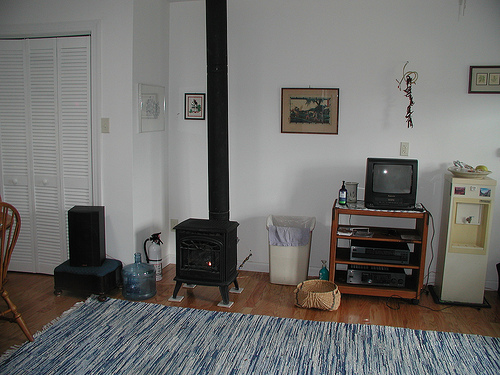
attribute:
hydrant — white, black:
[129, 225, 189, 286]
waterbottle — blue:
[121, 247, 158, 297]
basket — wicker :
[280, 248, 356, 315]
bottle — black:
[335, 180, 351, 207]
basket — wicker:
[290, 279, 341, 312]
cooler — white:
[436, 125, 498, 342]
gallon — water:
[117, 248, 161, 303]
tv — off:
[362, 155, 420, 213]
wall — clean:
[229, 8, 493, 300]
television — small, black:
[361, 152, 426, 220]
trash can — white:
[271, 212, 319, 289]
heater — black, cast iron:
[172, 0, 241, 305]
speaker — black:
[48, 200, 158, 292]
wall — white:
[134, 5, 499, 292]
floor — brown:
[2, 238, 499, 373]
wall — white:
[292, 15, 386, 72]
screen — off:
[372, 163, 413, 193]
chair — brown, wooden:
[0, 197, 36, 347]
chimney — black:
[153, 16, 262, 297]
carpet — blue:
[2, 289, 495, 370]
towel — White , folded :
[265, 223, 313, 245]